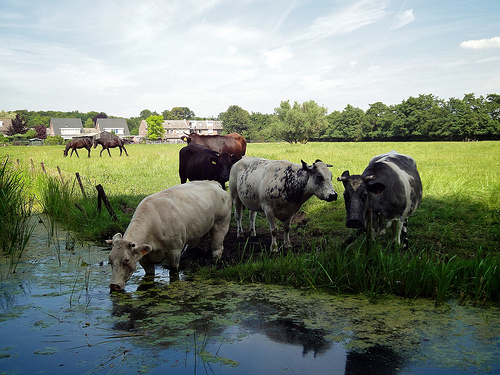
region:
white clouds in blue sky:
[16, 20, 51, 95]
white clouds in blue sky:
[57, 26, 104, 107]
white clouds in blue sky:
[120, 15, 157, 93]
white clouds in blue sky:
[160, 18, 208, 89]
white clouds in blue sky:
[214, 23, 256, 97]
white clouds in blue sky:
[231, 23, 282, 105]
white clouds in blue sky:
[276, 10, 311, 77]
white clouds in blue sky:
[311, 26, 369, 93]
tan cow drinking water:
[93, 172, 225, 302]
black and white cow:
[330, 135, 421, 252]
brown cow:
[179, 120, 249, 178]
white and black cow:
[231, 153, 329, 221]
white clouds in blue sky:
[56, 58, 87, 86]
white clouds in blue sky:
[134, 13, 171, 81]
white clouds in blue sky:
[236, 37, 278, 85]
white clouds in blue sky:
[284, 25, 332, 90]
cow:
[91, 175, 228, 292]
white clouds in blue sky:
[387, 14, 478, 66]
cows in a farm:
[3, 96, 480, 368]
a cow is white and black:
[328, 142, 439, 266]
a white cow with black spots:
[226, 148, 343, 260]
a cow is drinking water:
[81, 166, 239, 321]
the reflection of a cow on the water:
[237, 305, 337, 366]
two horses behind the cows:
[40, 120, 136, 181]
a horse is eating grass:
[52, 133, 95, 161]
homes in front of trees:
[10, 107, 228, 154]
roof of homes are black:
[43, 114, 133, 139]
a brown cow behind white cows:
[168, 123, 252, 189]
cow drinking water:
[99, 180, 234, 297]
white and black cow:
[331, 136, 422, 261]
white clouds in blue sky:
[9, 15, 41, 69]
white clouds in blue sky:
[39, 23, 79, 84]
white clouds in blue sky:
[106, 23, 123, 58]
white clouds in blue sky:
[186, 0, 230, 82]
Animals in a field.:
[5, 128, 490, 297]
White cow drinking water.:
[95, 182, 239, 303]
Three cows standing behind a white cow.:
[89, 127, 431, 287]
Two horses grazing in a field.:
[52, 130, 137, 170]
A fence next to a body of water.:
[1, 150, 123, 226]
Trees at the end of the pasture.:
[225, 99, 497, 146]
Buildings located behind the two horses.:
[36, 107, 236, 147]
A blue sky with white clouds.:
[4, 3, 486, 94]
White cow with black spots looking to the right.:
[226, 152, 346, 260]